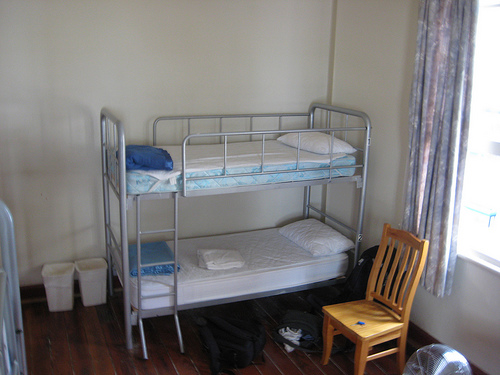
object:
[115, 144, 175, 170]
blanket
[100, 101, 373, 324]
bed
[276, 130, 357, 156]
pillow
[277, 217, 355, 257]
pillow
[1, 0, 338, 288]
wall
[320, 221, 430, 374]
chair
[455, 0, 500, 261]
window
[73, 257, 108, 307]
waste basket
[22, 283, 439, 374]
floor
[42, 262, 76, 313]
waste basket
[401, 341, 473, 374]
fan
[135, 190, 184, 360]
ladder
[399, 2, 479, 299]
curtain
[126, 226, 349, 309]
mattress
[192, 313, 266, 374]
back pack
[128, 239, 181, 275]
blanket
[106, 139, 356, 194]
mattress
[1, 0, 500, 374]
room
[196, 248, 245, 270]
sheet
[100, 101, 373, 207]
top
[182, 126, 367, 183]
guard rail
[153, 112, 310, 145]
guard rail